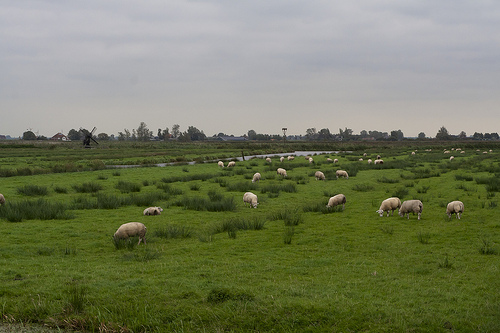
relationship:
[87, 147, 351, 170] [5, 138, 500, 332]
water running through field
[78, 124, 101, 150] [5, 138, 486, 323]
windmill in field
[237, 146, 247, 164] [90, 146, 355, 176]
post next to water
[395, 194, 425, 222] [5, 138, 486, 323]
sheep in field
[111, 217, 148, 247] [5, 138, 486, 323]
sheep grazing in field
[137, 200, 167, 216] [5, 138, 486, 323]
sheep grazing in field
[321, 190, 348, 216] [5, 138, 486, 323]
sheep grazing in field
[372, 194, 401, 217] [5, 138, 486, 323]
sheep grazing in field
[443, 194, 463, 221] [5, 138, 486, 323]
sheep grazing in field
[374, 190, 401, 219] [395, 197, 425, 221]
sheep standing next to sheep